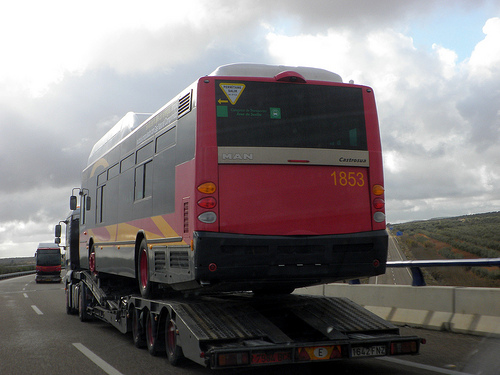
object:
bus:
[70, 62, 389, 299]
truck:
[53, 206, 425, 370]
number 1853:
[330, 170, 364, 189]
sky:
[0, 1, 498, 259]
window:
[213, 80, 369, 168]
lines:
[71, 342, 123, 375]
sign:
[219, 83, 247, 105]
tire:
[137, 236, 166, 298]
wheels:
[78, 281, 96, 323]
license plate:
[349, 345, 387, 359]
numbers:
[330, 170, 337, 186]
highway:
[0, 271, 499, 375]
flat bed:
[76, 269, 426, 370]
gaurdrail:
[291, 257, 500, 338]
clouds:
[0, 1, 499, 262]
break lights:
[372, 184, 387, 223]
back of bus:
[196, 69, 387, 281]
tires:
[164, 311, 187, 365]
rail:
[386, 258, 498, 267]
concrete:
[291, 284, 499, 336]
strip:
[86, 214, 189, 249]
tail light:
[196, 182, 217, 224]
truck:
[34, 242, 64, 282]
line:
[375, 355, 470, 375]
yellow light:
[372, 183, 385, 196]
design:
[88, 159, 190, 246]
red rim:
[139, 250, 147, 289]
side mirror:
[70, 187, 81, 210]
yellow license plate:
[294, 344, 342, 361]